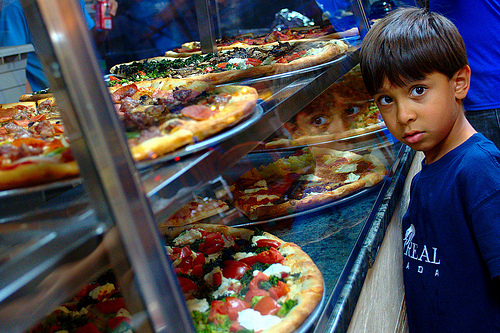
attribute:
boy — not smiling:
[348, 12, 499, 332]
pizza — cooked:
[231, 150, 385, 210]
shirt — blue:
[400, 150, 499, 332]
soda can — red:
[95, 1, 116, 31]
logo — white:
[396, 223, 445, 281]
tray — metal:
[191, 150, 386, 228]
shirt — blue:
[426, 0, 498, 105]